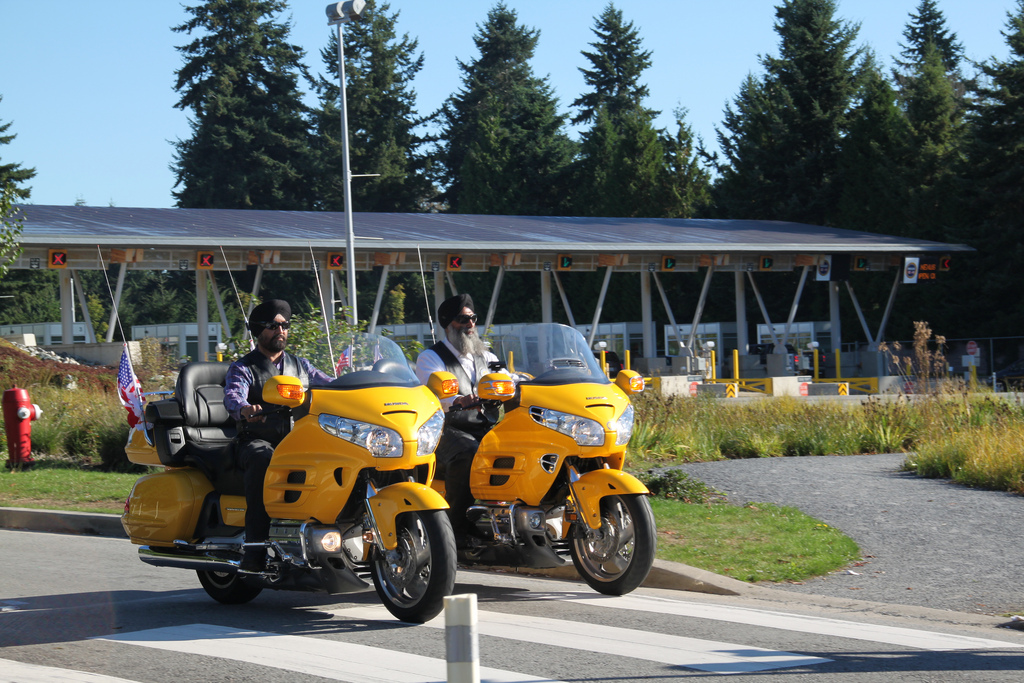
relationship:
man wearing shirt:
[411, 289, 528, 541] [419, 333, 509, 419]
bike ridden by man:
[120, 359, 459, 617] [225, 294, 331, 575]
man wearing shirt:
[225, 294, 331, 575] [224, 345, 348, 421]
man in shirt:
[411, 289, 528, 541] [410, 342, 521, 425]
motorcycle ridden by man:
[430, 320, 665, 597] [411, 289, 528, 541]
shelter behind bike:
[0, 206, 977, 407] [120, 359, 459, 617]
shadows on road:
[0, 566, 479, 650] [0, 509, 1022, 680]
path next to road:
[676, 443, 1022, 618] [0, 509, 1022, 680]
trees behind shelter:
[167, 0, 1019, 368] [3, 199, 983, 356]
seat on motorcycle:
[161, 358, 238, 460] [119, 329, 462, 624]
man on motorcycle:
[225, 294, 353, 576] [119, 329, 462, 624]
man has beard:
[411, 289, 528, 429] [443, 321, 486, 357]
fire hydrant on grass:
[0, 382, 43, 469] [2, 465, 149, 504]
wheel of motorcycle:
[363, 482, 462, 623] [119, 329, 462, 624]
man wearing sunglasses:
[225, 294, 331, 575] [258, 313, 304, 333]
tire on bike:
[351, 452, 460, 631] [120, 322, 460, 632]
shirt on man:
[218, 349, 327, 439] [218, 294, 317, 604]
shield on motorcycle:
[268, 308, 731, 415] [430, 320, 665, 597]